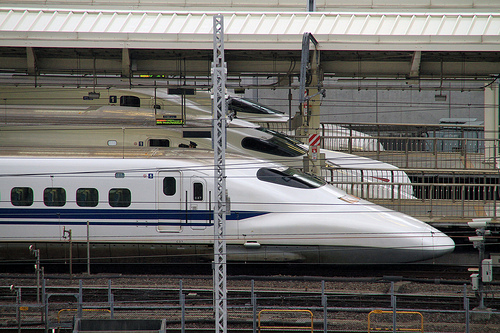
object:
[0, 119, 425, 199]
trains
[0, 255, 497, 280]
tracks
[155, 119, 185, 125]
billboard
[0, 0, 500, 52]
roof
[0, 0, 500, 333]
train station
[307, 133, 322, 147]
sign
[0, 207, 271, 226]
line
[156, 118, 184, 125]
electronic display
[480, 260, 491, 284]
sensors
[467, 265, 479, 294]
sensors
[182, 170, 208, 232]
door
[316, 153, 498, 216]
barriers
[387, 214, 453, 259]
tip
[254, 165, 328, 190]
windshield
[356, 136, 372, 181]
ground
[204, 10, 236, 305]
pole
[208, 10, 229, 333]
pillar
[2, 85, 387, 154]
train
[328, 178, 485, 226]
gate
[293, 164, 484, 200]
gate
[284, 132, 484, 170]
gate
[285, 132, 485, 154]
gate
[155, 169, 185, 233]
door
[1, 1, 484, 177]
building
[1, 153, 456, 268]
bullet train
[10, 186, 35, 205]
window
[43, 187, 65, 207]
window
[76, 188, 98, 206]
window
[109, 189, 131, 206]
window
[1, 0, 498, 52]
tiles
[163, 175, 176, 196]
window